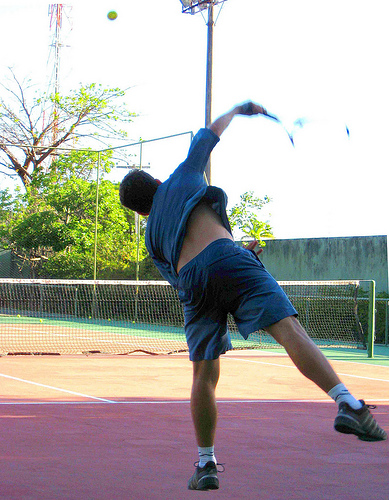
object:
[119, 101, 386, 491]
man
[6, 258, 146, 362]
red light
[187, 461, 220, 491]
shoe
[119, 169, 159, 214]
hair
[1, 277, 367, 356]
net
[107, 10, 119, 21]
ball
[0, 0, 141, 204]
tree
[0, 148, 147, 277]
tree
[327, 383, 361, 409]
sock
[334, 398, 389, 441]
right foot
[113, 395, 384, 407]
lines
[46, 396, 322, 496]
shadow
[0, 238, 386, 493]
court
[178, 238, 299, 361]
shorts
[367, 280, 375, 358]
pole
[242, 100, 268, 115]
hand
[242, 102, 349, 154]
racket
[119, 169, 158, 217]
head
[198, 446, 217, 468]
sock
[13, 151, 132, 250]
leaves